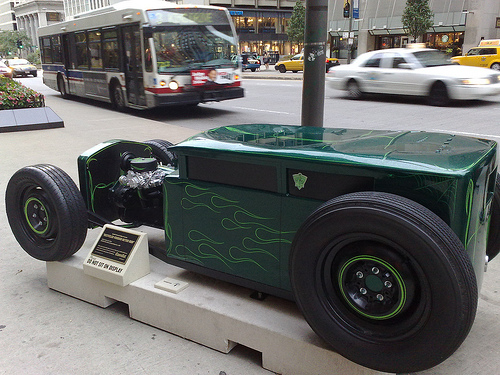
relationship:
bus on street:
[28, 13, 260, 105] [206, 10, 453, 122]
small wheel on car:
[3, 160, 85, 261] [4, 120, 498, 373]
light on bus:
[166, 78, 180, 90] [29, 8, 249, 113]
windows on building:
[373, 30, 461, 56] [325, 0, 415, 65]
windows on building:
[237, 11, 301, 55] [175, 0, 304, 66]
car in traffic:
[326, 47, 499, 106] [0, 52, 499, 122]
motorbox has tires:
[3, 112, 488, 372] [3, 160, 481, 374]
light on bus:
[168, 81, 179, 90] [290, 3, 329, 123]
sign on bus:
[191, 66, 240, 92] [37, 2, 247, 115]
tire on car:
[430, 81, 450, 106] [327, 36, 497, 105]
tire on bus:
[98, 77, 122, 118] [28, 10, 248, 97]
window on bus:
[102, 30, 119, 66] [37, 2, 247, 115]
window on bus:
[87, 32, 102, 68] [37, 2, 247, 115]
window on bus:
[71, 35, 88, 65] [37, 2, 247, 115]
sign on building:
[352, 0, 359, 22] [322, 2, 492, 39]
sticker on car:
[288, 167, 314, 192] [25, 107, 496, 346]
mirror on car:
[396, 59, 416, 71] [323, 41, 499, 109]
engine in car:
[117, 153, 166, 222] [4, 120, 498, 373]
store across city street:
[328, 3, 487, 61] [0, 0, 500, 147]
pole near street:
[296, 2, 327, 126] [301, 5, 326, 133]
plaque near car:
[87, 227, 142, 274] [4, 120, 498, 373]